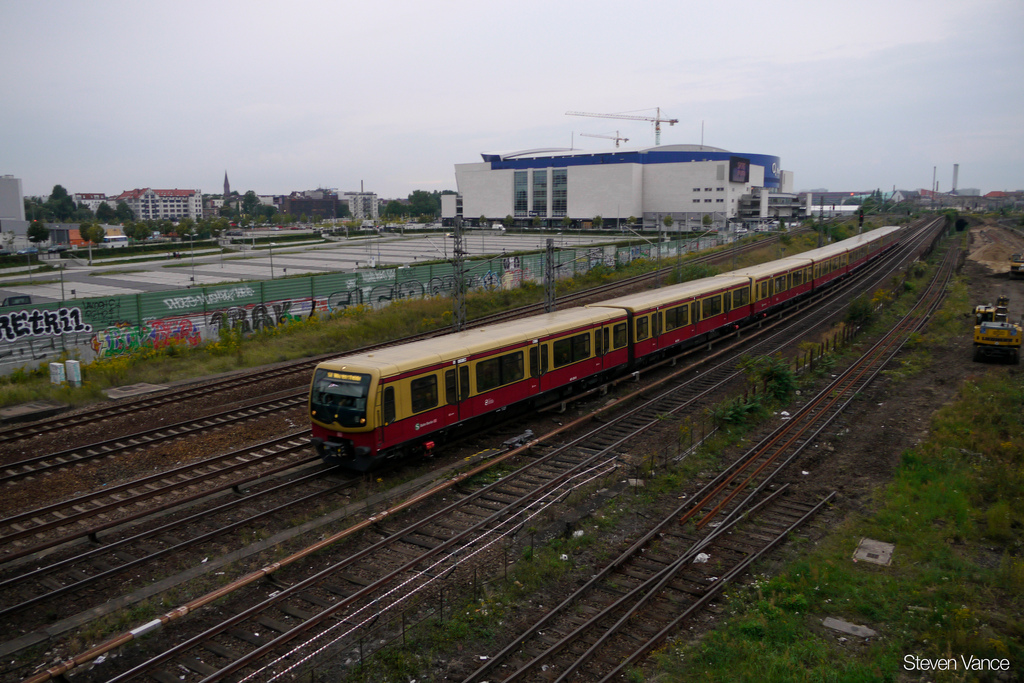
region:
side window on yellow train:
[378, 387, 398, 425]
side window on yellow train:
[408, 373, 439, 411]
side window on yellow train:
[473, 349, 527, 391]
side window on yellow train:
[527, 342, 551, 373]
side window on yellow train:
[549, 328, 589, 373]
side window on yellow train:
[592, 326, 612, 353]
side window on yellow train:
[610, 317, 630, 346]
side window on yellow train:
[633, 313, 653, 344]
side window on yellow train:
[648, 304, 668, 337]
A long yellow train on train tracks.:
[309, 221, 907, 468]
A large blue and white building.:
[452, 96, 785, 232]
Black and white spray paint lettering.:
[0, 295, 102, 352]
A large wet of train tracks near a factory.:
[2, 197, 971, 679]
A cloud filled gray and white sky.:
[3, 0, 1019, 200]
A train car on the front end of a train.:
[302, 301, 629, 475]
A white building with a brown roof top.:
[116, 183, 214, 232]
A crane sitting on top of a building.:
[561, 98, 686, 146]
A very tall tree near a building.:
[214, 165, 240, 223]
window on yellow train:
[375, 384, 398, 424]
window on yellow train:
[406, 370, 440, 417]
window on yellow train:
[441, 362, 473, 404]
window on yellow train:
[473, 345, 523, 393]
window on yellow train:
[551, 326, 594, 371]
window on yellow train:
[592, 321, 613, 355]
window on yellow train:
[610, 315, 637, 347]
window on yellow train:
[629, 313, 648, 342]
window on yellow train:
[647, 308, 668, 334]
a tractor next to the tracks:
[970, 297, 1018, 349]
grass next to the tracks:
[770, 562, 1011, 671]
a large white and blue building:
[439, 158, 766, 217]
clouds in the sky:
[9, 9, 968, 114]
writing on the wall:
[2, 303, 102, 345]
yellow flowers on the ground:
[78, 342, 154, 375]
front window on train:
[312, 364, 374, 437]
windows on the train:
[367, 339, 565, 407]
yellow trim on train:
[357, 217, 924, 437]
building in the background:
[439, 129, 773, 238]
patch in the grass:
[847, 511, 899, 581]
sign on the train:
[316, 357, 375, 392]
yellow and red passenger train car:
[268, 289, 658, 476]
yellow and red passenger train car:
[612, 262, 745, 357]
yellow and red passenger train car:
[742, 227, 878, 313]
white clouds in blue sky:
[110, 11, 254, 91]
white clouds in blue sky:
[440, 37, 524, 94]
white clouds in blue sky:
[666, 11, 750, 72]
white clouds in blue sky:
[813, 24, 957, 108]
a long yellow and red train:
[306, 221, 907, 466]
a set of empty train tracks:
[456, 224, 976, 678]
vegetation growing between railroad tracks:
[310, 218, 972, 680]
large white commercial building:
[439, 133, 814, 235]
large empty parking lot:
[0, 219, 653, 303]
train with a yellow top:
[300, 225, 901, 472]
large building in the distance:
[111, 180, 210, 245]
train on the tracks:
[304, 215, 919, 469]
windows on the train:
[332, 361, 509, 413]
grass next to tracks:
[759, 416, 1000, 663]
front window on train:
[303, 364, 384, 440]